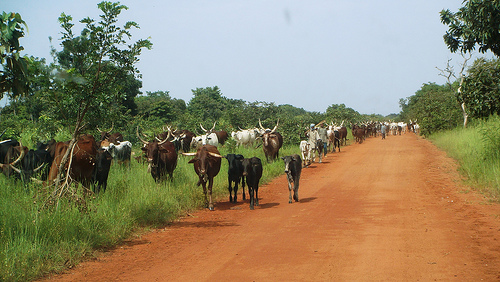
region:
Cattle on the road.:
[87, 71, 368, 246]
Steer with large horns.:
[131, 87, 372, 267]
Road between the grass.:
[236, 105, 421, 186]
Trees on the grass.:
[30, 20, 191, 220]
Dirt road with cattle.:
[247, 116, 486, 265]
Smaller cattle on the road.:
[234, 151, 291, 198]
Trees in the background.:
[185, 57, 345, 165]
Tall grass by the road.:
[71, 174, 222, 261]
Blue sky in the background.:
[233, 6, 428, 144]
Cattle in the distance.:
[349, 96, 434, 162]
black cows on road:
[219, 135, 261, 199]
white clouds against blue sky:
[22, 15, 45, 48]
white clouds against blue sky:
[136, 8, 191, 43]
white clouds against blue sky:
[164, 58, 194, 88]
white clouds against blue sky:
[200, 62, 247, 89]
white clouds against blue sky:
[253, 63, 304, 90]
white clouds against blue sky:
[313, 60, 390, 102]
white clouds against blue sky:
[368, 20, 443, 56]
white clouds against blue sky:
[236, 13, 290, 53]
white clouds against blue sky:
[294, 4, 380, 49]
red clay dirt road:
[371, 145, 461, 236]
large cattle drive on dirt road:
[129, 118, 414, 211]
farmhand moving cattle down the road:
[368, 114, 413, 141]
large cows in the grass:
[38, 117, 180, 197]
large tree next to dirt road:
[415, 54, 481, 176]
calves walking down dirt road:
[222, 147, 306, 212]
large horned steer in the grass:
[129, 122, 226, 211]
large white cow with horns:
[226, 121, 257, 151]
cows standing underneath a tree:
[9, 19, 121, 203]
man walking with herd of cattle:
[349, 116, 398, 144]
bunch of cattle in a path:
[2, 108, 420, 200]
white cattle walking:
[99, 118, 415, 173]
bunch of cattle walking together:
[0, 115, 415, 211]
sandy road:
[37, 121, 493, 276]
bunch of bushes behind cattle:
[0, 59, 497, 141]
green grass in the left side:
[0, 110, 335, 275]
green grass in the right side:
[425, 105, 495, 205]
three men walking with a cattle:
[305, 120, 388, 162]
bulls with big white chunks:
[5, 117, 355, 199]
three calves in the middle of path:
[224, 152, 303, 206]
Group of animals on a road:
[147, 108, 339, 230]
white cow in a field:
[213, 119, 273, 146]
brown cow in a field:
[194, 140, 220, 195]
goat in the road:
[283, 150, 311, 204]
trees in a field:
[42, 49, 147, 119]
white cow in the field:
[232, 128, 279, 158]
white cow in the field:
[298, 120, 318, 166]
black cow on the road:
[224, 145, 291, 208]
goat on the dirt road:
[281, 147, 318, 194]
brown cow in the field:
[46, 112, 124, 197]